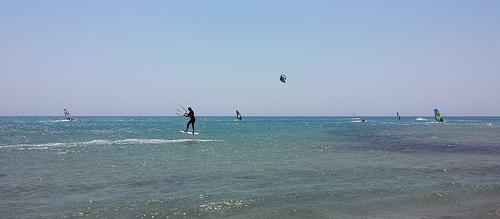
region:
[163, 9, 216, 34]
part of the sky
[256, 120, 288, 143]
part of a water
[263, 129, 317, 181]
part of a water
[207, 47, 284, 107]
part of the sky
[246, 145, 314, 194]
part of a shore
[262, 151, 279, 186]
the water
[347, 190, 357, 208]
the water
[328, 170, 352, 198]
the water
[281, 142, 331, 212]
the water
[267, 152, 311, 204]
the water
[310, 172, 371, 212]
the water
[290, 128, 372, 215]
the water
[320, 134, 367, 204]
the water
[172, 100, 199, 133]
This is a person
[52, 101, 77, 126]
This is a dhow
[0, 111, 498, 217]
This is an ocean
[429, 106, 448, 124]
This is a dhow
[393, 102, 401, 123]
This is a dhow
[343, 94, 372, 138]
This is a dhow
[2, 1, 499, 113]
This is sky line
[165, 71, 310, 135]
This is a person flying a kite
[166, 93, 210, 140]
This is a man running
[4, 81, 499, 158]
This is a skyline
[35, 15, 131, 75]
sky is blue and hazy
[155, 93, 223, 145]
person is on kiteboard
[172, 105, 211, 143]
man on white kiteboard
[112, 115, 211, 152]
small waves on water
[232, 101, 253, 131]
boat out on water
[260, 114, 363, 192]
water is blue and calm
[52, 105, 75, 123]
boat is making waves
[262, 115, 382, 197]
water is bright blue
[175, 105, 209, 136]
person wears black wetsuit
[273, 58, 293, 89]
dark kite in air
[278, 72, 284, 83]
a small kite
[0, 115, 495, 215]
blue and white water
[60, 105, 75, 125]
a sail boat on left side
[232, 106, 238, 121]
a red and white sail boat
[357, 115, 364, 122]
a speeding motor boat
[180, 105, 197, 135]
a man on surf board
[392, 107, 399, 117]
a small sail boat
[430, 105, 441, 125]
a blue, yellow and white sail boat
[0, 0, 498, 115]
a blue and gray sky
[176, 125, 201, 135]
a white surf board